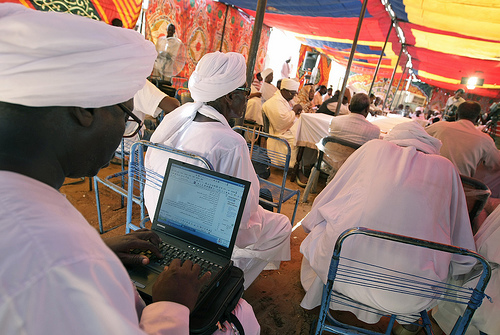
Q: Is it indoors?
A: Yes, it is indoors.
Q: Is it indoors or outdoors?
A: It is indoors.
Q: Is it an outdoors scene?
A: No, it is indoors.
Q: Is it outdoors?
A: No, it is indoors.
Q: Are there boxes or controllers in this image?
A: No, there are no boxes or controllers.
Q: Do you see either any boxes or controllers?
A: No, there are no boxes or controllers.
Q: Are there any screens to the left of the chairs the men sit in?
A: Yes, there is a screen to the left of the chairs.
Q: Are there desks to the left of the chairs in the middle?
A: No, there is a screen to the left of the chairs.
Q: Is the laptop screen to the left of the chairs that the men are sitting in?
A: Yes, the screen is to the left of the chairs.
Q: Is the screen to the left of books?
A: No, the screen is to the left of the chairs.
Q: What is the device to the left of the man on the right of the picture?
A: The device is a screen.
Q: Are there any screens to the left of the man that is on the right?
A: Yes, there is a screen to the left of the man.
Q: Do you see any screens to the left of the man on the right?
A: Yes, there is a screen to the left of the man.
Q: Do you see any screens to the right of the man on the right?
A: No, the screen is to the left of the man.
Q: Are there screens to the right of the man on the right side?
A: No, the screen is to the left of the man.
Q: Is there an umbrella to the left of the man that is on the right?
A: No, there is a screen to the left of the man.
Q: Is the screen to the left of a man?
A: Yes, the screen is to the left of a man.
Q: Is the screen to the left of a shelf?
A: No, the screen is to the left of a man.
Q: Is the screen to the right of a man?
A: No, the screen is to the left of a man.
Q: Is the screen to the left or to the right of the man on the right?
A: The screen is to the left of the man.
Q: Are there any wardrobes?
A: No, there are no wardrobes.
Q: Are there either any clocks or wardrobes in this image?
A: No, there are no wardrobes or clocks.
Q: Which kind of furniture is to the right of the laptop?
A: The pieces of furniture are chairs.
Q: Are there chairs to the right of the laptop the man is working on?
A: Yes, there are chairs to the right of the laptop.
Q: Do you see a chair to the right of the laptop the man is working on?
A: Yes, there are chairs to the right of the laptop.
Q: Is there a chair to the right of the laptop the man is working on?
A: Yes, there are chairs to the right of the laptop.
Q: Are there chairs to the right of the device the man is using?
A: Yes, there are chairs to the right of the laptop.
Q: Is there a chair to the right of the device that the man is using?
A: Yes, there are chairs to the right of the laptop.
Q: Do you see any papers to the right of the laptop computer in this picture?
A: No, there are chairs to the right of the laptop computer.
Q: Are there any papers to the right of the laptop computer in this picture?
A: No, there are chairs to the right of the laptop computer.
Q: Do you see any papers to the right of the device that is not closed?
A: No, there are chairs to the right of the laptop computer.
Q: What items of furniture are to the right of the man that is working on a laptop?
A: The pieces of furniture are chairs.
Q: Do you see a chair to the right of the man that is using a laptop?
A: Yes, there are chairs to the right of the man.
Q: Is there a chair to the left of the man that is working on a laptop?
A: No, the chairs are to the right of the man.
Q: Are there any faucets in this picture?
A: No, there are no faucets.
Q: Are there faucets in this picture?
A: No, there are no faucets.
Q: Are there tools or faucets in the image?
A: No, there are no faucets or tools.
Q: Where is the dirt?
A: The dirt is on the floor.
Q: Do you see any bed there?
A: No, there are no beds.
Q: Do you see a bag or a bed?
A: No, there are no beds or bags.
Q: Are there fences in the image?
A: No, there are no fences.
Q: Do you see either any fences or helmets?
A: No, there are no fences or helmets.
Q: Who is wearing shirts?
A: The men are wearing shirts.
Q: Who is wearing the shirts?
A: The men are wearing shirts.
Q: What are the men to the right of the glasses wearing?
A: The men are wearing shirts.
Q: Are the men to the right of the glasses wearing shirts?
A: Yes, the men are wearing shirts.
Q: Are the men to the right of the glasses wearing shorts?
A: No, the men are wearing shirts.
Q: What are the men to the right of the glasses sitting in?
A: The men are sitting in the chairs.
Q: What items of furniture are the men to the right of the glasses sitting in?
A: The men are sitting in the chairs.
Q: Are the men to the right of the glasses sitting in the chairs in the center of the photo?
A: Yes, the men are sitting in the chairs.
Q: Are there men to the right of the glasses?
A: Yes, there are men to the right of the glasses.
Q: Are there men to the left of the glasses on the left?
A: No, the men are to the right of the glasses.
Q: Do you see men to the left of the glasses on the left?
A: No, the men are to the right of the glasses.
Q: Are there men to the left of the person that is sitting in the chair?
A: Yes, there are men to the left of the person.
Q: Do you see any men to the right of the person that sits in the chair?
A: No, the men are to the left of the person.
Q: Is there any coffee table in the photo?
A: No, there are no coffee tables.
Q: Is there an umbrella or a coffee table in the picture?
A: No, there are no coffee tables or umbrellas.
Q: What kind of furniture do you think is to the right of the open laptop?
A: The pieces of furniture are chairs.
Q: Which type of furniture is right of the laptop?
A: The pieces of furniture are chairs.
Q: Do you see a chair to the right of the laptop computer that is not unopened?
A: Yes, there are chairs to the right of the laptop.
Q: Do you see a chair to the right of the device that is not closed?
A: Yes, there are chairs to the right of the laptop.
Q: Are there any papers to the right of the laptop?
A: No, there are chairs to the right of the laptop.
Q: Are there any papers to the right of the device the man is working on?
A: No, there are chairs to the right of the laptop.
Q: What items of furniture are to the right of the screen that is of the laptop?
A: The pieces of furniture are chairs.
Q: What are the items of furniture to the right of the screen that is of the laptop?
A: The pieces of furniture are chairs.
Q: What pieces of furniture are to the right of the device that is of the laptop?
A: The pieces of furniture are chairs.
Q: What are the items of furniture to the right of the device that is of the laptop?
A: The pieces of furniture are chairs.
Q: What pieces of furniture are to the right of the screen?
A: The pieces of furniture are chairs.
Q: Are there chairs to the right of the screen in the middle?
A: Yes, there are chairs to the right of the screen.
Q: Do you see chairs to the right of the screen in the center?
A: Yes, there are chairs to the right of the screen.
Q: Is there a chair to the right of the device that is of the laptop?
A: Yes, there are chairs to the right of the screen.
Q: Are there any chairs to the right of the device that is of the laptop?
A: Yes, there are chairs to the right of the screen.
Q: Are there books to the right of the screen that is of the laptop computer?
A: No, there are chairs to the right of the screen.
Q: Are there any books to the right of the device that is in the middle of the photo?
A: No, there are chairs to the right of the screen.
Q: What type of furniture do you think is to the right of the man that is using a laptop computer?
A: The pieces of furniture are chairs.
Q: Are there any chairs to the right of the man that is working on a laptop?
A: Yes, there are chairs to the right of the man.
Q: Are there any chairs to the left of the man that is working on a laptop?
A: No, the chairs are to the right of the man.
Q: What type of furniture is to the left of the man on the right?
A: The pieces of furniture are chairs.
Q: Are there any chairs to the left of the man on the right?
A: Yes, there are chairs to the left of the man.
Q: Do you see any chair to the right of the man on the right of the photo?
A: No, the chairs are to the left of the man.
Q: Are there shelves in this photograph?
A: No, there are no shelves.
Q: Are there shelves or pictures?
A: No, there are no shelves or pictures.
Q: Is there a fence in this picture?
A: No, there are no fences.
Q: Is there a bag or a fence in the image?
A: No, there are no fences or bags.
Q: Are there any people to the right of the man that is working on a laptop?
A: Yes, there is a person to the right of the man.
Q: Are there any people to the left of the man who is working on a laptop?
A: No, the person is to the right of the man.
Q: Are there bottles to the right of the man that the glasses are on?
A: No, there is a person to the right of the man.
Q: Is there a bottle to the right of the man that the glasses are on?
A: No, there is a person to the right of the man.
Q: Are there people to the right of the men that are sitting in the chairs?
A: Yes, there is a person to the right of the men.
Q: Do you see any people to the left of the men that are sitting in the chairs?
A: No, the person is to the right of the men.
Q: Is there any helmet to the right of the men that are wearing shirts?
A: No, there is a person to the right of the men.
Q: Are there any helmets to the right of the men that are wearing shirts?
A: No, there is a person to the right of the men.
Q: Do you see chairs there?
A: Yes, there is a chair.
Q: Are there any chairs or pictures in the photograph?
A: Yes, there is a chair.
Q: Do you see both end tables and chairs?
A: No, there is a chair but no end tables.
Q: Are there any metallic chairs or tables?
A: Yes, there is a metal chair.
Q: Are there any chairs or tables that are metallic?
A: Yes, the chair is metallic.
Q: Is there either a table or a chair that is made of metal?
A: Yes, the chair is made of metal.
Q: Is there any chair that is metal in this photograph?
A: Yes, there is a metal chair.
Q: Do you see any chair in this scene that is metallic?
A: Yes, there is a chair that is metallic.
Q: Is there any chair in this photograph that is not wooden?
A: Yes, there is a metallic chair.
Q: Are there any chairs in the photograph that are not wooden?
A: Yes, there is a metallic chair.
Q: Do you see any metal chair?
A: Yes, there is a chair that is made of metal.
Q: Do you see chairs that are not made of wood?
A: Yes, there is a chair that is made of metal.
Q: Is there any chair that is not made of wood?
A: Yes, there is a chair that is made of metal.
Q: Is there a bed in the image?
A: No, there are no beds.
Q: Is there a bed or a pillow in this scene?
A: No, there are no beds or pillows.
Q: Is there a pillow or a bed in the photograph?
A: No, there are no beds or pillows.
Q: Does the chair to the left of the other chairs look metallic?
A: Yes, the chair is metallic.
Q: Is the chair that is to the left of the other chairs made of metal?
A: Yes, the chair is made of metal.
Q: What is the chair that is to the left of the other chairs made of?
A: The chair is made of metal.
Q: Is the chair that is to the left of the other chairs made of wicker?
A: No, the chair is made of metal.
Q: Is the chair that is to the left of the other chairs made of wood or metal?
A: The chair is made of metal.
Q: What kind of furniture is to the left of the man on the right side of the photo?
A: The piece of furniture is a chair.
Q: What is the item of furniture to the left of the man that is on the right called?
A: The piece of furniture is a chair.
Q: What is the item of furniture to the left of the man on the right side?
A: The piece of furniture is a chair.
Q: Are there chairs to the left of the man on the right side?
A: Yes, there is a chair to the left of the man.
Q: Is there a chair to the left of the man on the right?
A: Yes, there is a chair to the left of the man.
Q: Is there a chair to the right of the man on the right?
A: No, the chair is to the left of the man.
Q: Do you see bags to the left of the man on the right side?
A: No, there is a chair to the left of the man.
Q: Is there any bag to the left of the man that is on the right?
A: No, there is a chair to the left of the man.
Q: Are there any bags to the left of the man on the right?
A: No, there is a chair to the left of the man.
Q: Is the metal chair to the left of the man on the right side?
A: Yes, the chair is to the left of the man.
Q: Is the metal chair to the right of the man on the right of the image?
A: No, the chair is to the left of the man.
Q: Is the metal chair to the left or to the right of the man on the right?
A: The chair is to the left of the man.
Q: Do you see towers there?
A: No, there are no towers.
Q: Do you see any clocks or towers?
A: No, there are no towers or clocks.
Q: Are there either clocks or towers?
A: No, there are no towers or clocks.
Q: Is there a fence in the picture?
A: No, there are no fences.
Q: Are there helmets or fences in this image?
A: No, there are no fences or helmets.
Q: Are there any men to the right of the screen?
A: Yes, there is a man to the right of the screen.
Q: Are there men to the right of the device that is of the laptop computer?
A: Yes, there is a man to the right of the screen.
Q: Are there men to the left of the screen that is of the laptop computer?
A: No, the man is to the right of the screen.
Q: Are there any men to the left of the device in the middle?
A: No, the man is to the right of the screen.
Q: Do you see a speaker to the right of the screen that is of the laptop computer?
A: No, there is a man to the right of the screen.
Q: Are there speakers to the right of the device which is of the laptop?
A: No, there is a man to the right of the screen.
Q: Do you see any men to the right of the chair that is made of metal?
A: Yes, there is a man to the right of the chair.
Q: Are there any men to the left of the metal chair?
A: No, the man is to the right of the chair.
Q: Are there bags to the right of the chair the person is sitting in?
A: No, there is a man to the right of the chair.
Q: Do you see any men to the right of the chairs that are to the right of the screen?
A: Yes, there is a man to the right of the chairs.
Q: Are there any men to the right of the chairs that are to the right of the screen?
A: Yes, there is a man to the right of the chairs.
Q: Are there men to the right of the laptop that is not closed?
A: Yes, there is a man to the right of the laptop.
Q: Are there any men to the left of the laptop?
A: No, the man is to the right of the laptop.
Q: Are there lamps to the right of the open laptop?
A: No, there is a man to the right of the laptop.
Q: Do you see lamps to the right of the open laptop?
A: No, there is a man to the right of the laptop.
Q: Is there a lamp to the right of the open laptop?
A: No, there is a man to the right of the laptop.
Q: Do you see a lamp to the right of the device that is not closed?
A: No, there is a man to the right of the laptop.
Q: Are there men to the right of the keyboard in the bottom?
A: Yes, there is a man to the right of the keyboard.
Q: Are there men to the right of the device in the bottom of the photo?
A: Yes, there is a man to the right of the keyboard.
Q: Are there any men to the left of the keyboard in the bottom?
A: No, the man is to the right of the keyboard.